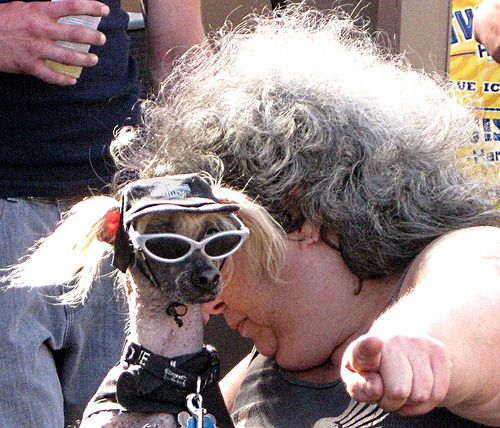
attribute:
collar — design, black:
[106, 346, 237, 408]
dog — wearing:
[41, 116, 292, 427]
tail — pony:
[34, 187, 118, 262]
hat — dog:
[81, 130, 285, 246]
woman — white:
[171, 15, 456, 414]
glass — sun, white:
[139, 193, 273, 271]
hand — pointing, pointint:
[292, 280, 456, 419]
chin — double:
[240, 294, 347, 394]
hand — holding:
[29, 5, 115, 105]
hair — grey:
[274, 66, 333, 139]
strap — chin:
[138, 284, 213, 361]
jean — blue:
[33, 239, 150, 424]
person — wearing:
[3, 75, 163, 398]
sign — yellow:
[449, 10, 484, 77]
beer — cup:
[49, 12, 91, 91]